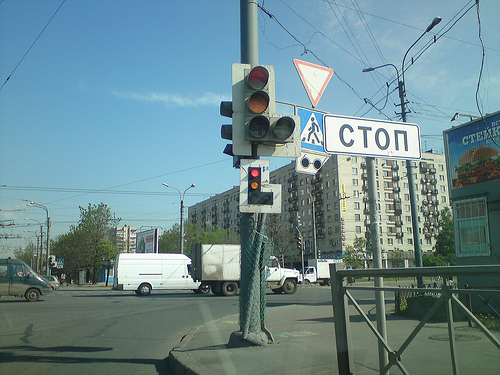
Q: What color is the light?
A: Red.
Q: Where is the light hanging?
A: Pole.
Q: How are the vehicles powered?
A: Engines.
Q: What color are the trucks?
A: White.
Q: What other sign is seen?
A: Yield.